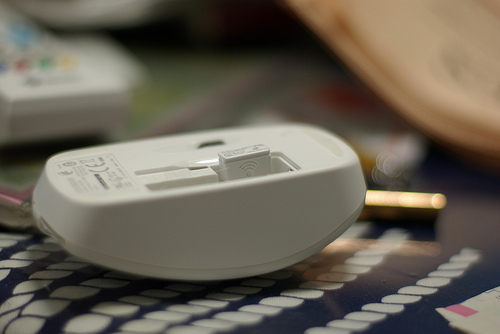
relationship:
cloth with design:
[11, 281, 499, 331] [388, 245, 481, 319]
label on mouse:
[51, 150, 135, 197] [26, 112, 373, 289]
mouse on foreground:
[26, 112, 373, 289] [2, 154, 498, 332]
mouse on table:
[26, 112, 373, 289] [13, 113, 489, 323]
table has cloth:
[132, 31, 495, 240] [162, 53, 256, 91]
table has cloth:
[0, 0, 500, 334] [132, 40, 344, 121]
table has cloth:
[0, 0, 500, 334] [150, 20, 248, 96]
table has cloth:
[0, 0, 500, 334] [172, 60, 255, 92]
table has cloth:
[0, 0, 500, 334] [139, 20, 224, 83]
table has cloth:
[0, 0, 500, 334] [146, 14, 498, 237]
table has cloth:
[0, 0, 500, 334] [168, 47, 242, 90]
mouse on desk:
[27, 121, 372, 289] [1, 4, 497, 329]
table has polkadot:
[0, 0, 500, 334] [232, 280, 410, 325]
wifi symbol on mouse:
[204, 135, 285, 182] [27, 121, 372, 289]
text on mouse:
[52, 148, 139, 200] [27, 121, 372, 289]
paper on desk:
[430, 282, 499, 331] [1, 4, 497, 329]